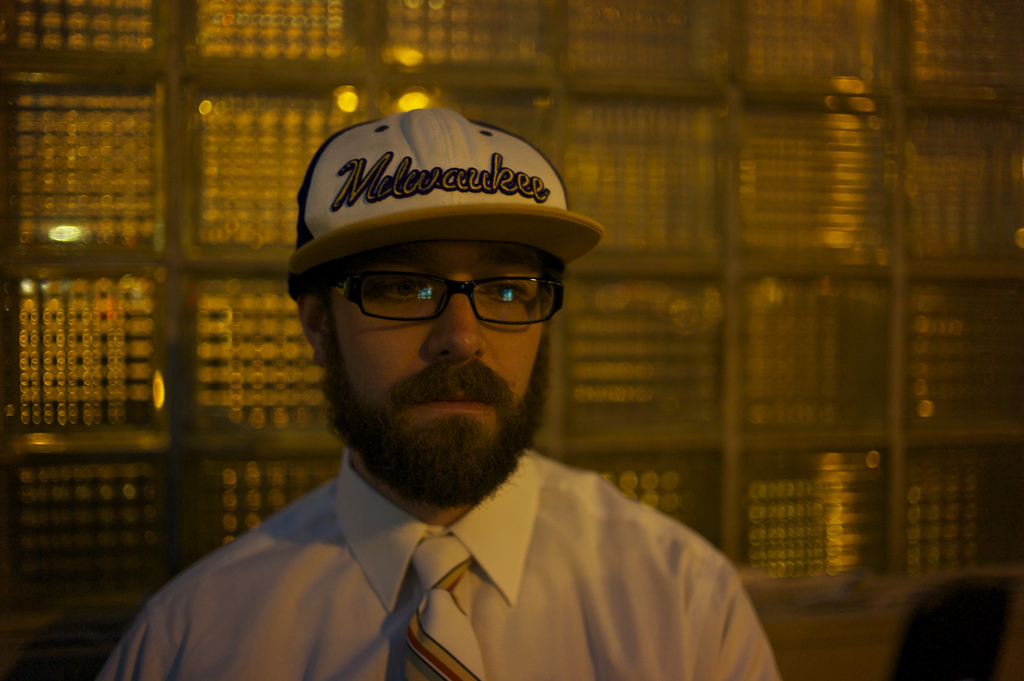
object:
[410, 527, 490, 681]
tie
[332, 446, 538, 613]
collar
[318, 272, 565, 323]
glasses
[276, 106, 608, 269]
cap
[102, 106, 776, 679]
man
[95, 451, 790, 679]
dress shirt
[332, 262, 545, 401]
face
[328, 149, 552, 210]
letters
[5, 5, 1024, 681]
wall